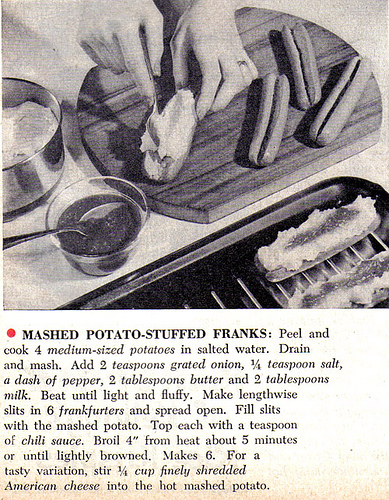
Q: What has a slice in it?
A: Hot dogs.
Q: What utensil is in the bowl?
A: Spoon.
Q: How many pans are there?
A: 1.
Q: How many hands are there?
A: 2.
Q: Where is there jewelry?
A: Finger.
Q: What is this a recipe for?
A: Mashed potato-stuffed franks.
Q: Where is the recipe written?
A: Under picture.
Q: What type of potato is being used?
A: Mashed.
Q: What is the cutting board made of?
A: Wood.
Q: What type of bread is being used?
A: Hot dog buns.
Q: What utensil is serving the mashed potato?
A: Spoon.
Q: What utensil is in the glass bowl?
A: Spoon.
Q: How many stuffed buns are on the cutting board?
A: One.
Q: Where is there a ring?
A: Woman's hand.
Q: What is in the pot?
A: Mashed potatoes.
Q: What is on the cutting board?
A: Hot dogs.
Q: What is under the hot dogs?
A: A wooden cutting board.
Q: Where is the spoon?
A: In the glass dish.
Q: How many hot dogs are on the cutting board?
A: Three.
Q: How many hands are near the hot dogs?
A: Two.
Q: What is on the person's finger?
A: A ring.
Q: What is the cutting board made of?
A: Wood.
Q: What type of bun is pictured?
A: Hot dog buns.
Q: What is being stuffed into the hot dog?
A: Mashed potatoes.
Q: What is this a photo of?
A: A recipe.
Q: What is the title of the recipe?
A: Mashed Potato-stuffed franks.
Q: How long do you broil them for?
A: About 5 minutes.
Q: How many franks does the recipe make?
A: Six.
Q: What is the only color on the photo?
A: Red.